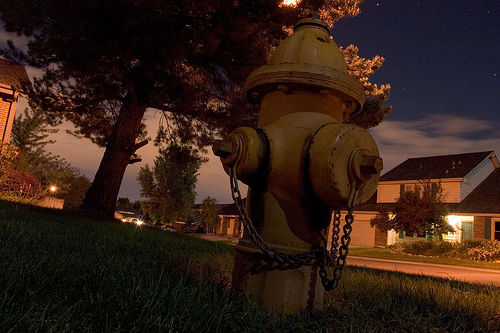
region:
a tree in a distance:
[20, 107, 60, 149]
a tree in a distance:
[137, 137, 203, 224]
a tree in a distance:
[201, 197, 223, 239]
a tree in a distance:
[118, 194, 133, 216]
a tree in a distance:
[133, 200, 141, 211]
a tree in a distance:
[130, 196, 139, 213]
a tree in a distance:
[382, 185, 458, 267]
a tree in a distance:
[7, 165, 44, 205]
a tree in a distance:
[63, 165, 91, 210]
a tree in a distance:
[29, 2, 391, 265]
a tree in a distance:
[134, 153, 166, 220]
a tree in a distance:
[195, 183, 223, 229]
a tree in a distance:
[35, 149, 72, 196]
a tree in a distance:
[56, 143, 84, 202]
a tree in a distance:
[1, 135, 18, 195]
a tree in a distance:
[340, 44, 392, 134]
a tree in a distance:
[468, 238, 489, 266]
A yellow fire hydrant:
[210, 14, 384, 321]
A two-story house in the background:
[330, 147, 497, 264]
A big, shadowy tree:
[1, 1, 388, 223]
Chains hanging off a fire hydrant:
[218, 165, 358, 285]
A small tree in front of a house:
[374, 179, 448, 251]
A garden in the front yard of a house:
[391, 236, 498, 263]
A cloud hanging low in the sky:
[359, 115, 496, 154]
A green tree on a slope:
[136, 142, 198, 229]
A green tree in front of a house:
[196, 197, 220, 234]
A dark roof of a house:
[381, 150, 498, 179]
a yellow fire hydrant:
[211, 15, 402, 315]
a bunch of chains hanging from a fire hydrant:
[221, 148, 371, 290]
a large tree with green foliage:
[19, 0, 239, 226]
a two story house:
[392, 150, 494, 249]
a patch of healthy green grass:
[18, 208, 152, 321]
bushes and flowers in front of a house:
[393, 232, 498, 272]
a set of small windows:
[393, 183, 444, 200]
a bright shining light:
[45, 162, 71, 209]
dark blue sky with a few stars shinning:
[372, 0, 498, 114]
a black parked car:
[181, 215, 217, 238]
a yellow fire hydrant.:
[187, 28, 424, 325]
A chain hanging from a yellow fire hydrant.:
[320, 181, 375, 273]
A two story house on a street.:
[326, 141, 498, 261]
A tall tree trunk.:
[44, 56, 174, 236]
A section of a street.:
[400, 251, 468, 285]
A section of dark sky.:
[377, 37, 460, 89]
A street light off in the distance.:
[36, 176, 63, 210]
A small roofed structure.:
[0, 53, 54, 139]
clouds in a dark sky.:
[411, 91, 472, 141]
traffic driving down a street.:
[109, 214, 161, 245]